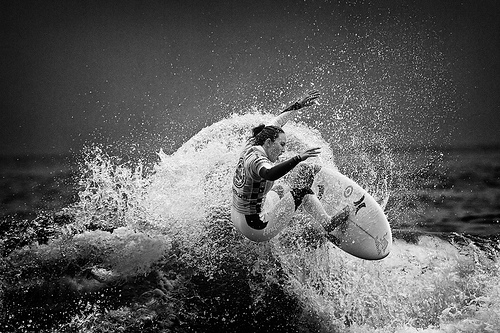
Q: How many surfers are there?
A: 1.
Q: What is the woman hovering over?
A: The ocean.